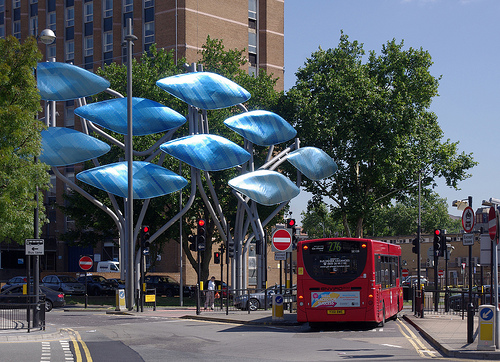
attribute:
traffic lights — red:
[134, 216, 454, 261]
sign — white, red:
[268, 227, 295, 252]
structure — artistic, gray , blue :
[37, 45, 336, 236]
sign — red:
[264, 226, 298, 256]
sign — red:
[73, 253, 97, 273]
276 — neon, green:
[327, 238, 342, 255]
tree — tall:
[273, 23, 478, 237]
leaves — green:
[327, 61, 395, 126]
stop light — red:
[430, 227, 445, 257]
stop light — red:
[185, 217, 207, 249]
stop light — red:
[283, 217, 297, 249]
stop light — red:
[137, 223, 153, 257]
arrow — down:
[480, 306, 495, 321]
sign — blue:
[479, 305, 496, 322]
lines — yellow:
[59, 320, 92, 359]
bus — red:
[220, 206, 451, 330]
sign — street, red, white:
[272, 227, 289, 251]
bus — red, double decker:
[287, 232, 405, 330]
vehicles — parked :
[42, 254, 267, 324]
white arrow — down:
[474, 303, 498, 350]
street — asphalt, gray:
[176, 327, 275, 359]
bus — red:
[279, 234, 417, 328]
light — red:
[428, 228, 445, 260]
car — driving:
[2, 280, 67, 313]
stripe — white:
[273, 234, 291, 246]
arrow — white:
[475, 301, 495, 321]